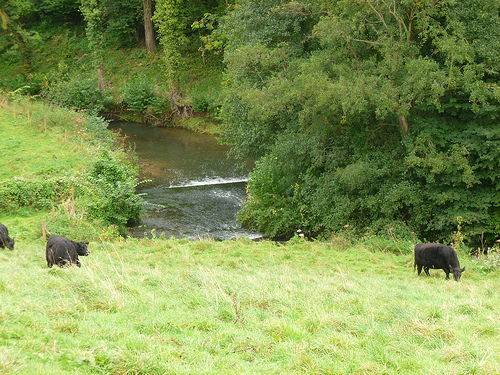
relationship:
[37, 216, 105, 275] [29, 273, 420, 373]
cow walking on grass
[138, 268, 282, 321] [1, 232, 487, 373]
grass on top of field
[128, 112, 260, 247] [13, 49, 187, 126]
water flowing down hill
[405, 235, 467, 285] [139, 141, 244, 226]
cow standing by water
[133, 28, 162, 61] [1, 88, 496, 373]
tree trunk growing from bank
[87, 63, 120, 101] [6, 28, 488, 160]
tree trunk growing from bank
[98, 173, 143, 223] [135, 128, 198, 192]
fern growing above water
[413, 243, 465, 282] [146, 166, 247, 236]
cow standing by water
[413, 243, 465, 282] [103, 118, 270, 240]
cow standing by water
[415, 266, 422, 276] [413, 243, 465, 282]
leg underneath cow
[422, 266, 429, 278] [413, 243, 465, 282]
leg underneath cow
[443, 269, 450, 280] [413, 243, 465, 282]
leg underneath cow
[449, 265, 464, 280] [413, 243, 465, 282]
head of cow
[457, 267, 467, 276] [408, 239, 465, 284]
ear of cow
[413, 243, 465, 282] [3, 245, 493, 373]
cow eating grass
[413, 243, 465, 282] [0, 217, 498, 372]
cow in grass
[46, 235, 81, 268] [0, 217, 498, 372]
cow in grass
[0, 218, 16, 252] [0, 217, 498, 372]
cow in grass